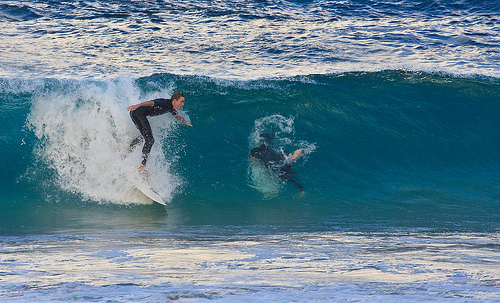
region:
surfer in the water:
[96, 53, 229, 166]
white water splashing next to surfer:
[70, 118, 131, 168]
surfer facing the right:
[114, 73, 216, 177]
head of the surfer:
[158, 86, 190, 121]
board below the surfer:
[104, 163, 166, 238]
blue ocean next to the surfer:
[331, 126, 449, 200]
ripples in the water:
[232, 25, 322, 69]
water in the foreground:
[265, 268, 308, 290]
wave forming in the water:
[277, 46, 372, 176]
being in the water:
[229, 118, 322, 210]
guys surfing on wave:
[16, 63, 371, 245]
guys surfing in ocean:
[0, 74, 333, 231]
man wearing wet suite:
[137, 68, 196, 133]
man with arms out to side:
[119, 91, 208, 124]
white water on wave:
[33, 61, 198, 211]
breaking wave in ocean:
[34, 16, 180, 191]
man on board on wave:
[193, 111, 308, 198]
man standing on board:
[60, 76, 201, 227]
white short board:
[88, 179, 167, 213]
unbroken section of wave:
[205, 61, 441, 259]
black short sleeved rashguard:
[114, 97, 181, 161]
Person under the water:
[246, 126, 311, 201]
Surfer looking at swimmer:
[156, 91, 305, 185]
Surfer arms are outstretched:
[126, 99, 202, 135]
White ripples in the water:
[30, 92, 141, 207]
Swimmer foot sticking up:
[281, 145, 308, 168]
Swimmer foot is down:
[293, 177, 309, 204]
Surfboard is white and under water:
[85, 138, 172, 227]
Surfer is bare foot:
[136, 152, 153, 191]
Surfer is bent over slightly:
[96, 80, 204, 152]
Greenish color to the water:
[328, 98, 488, 223]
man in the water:
[115, 68, 206, 190]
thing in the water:
[226, 98, 338, 193]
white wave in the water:
[57, 111, 121, 169]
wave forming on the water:
[353, 63, 430, 140]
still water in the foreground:
[238, 247, 303, 297]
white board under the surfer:
[128, 174, 180, 219]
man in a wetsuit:
[96, 87, 198, 157]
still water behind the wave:
[200, 5, 272, 48]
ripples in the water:
[231, 8, 294, 38]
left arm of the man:
[168, 113, 200, 136]